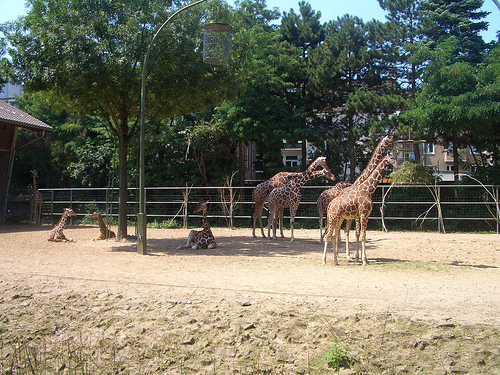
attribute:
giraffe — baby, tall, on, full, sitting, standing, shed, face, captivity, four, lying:
[52, 202, 93, 243]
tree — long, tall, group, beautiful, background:
[93, 7, 181, 236]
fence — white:
[137, 162, 252, 229]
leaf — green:
[229, 56, 263, 91]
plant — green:
[200, 112, 237, 146]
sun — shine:
[325, 11, 352, 21]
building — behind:
[411, 122, 461, 166]